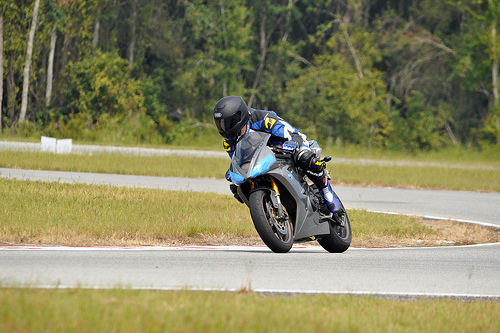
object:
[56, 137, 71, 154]
sign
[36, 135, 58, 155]
sign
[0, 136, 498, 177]
road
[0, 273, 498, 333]
grass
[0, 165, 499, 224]
road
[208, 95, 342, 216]
person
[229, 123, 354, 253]
motorcycle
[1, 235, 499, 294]
road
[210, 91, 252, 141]
helmet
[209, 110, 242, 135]
visor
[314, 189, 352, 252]
tires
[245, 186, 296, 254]
tires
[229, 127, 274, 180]
windshield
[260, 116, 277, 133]
patch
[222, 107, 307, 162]
jacket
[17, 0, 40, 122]
trunks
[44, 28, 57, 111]
trunks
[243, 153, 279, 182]
stripe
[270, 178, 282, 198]
pole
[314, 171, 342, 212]
boot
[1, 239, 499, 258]
edge